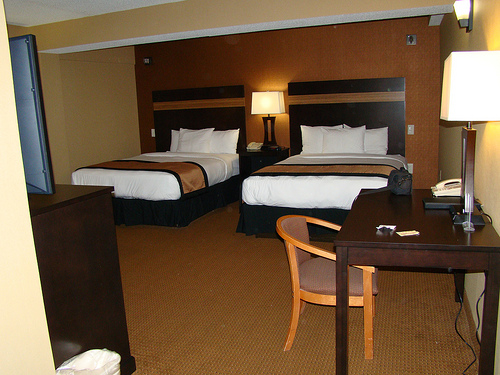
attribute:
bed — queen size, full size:
[70, 80, 246, 229]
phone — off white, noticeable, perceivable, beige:
[428, 177, 465, 197]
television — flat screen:
[6, 32, 59, 199]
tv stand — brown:
[24, 181, 137, 374]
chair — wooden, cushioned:
[271, 210, 382, 363]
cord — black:
[474, 276, 488, 350]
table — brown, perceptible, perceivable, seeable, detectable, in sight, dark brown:
[332, 186, 499, 374]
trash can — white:
[54, 345, 125, 374]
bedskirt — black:
[96, 173, 246, 229]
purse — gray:
[388, 166, 416, 201]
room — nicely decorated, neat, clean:
[2, 2, 499, 373]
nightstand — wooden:
[235, 148, 292, 216]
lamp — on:
[440, 48, 500, 228]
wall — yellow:
[28, 1, 449, 373]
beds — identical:
[70, 75, 410, 243]